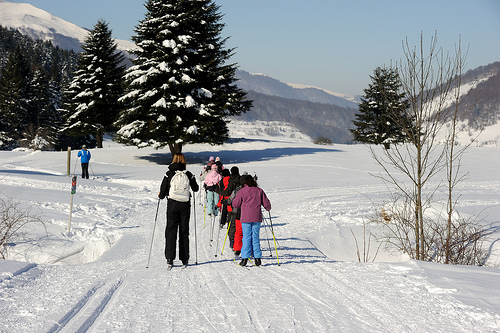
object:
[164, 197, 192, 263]
pants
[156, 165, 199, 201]
jacket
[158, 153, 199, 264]
woman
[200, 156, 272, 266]
people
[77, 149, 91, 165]
jacket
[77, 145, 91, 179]
man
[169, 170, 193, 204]
backpack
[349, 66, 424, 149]
tree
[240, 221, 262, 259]
pants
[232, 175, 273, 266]
person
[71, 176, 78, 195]
sign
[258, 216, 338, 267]
shadows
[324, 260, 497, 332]
snow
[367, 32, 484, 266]
bush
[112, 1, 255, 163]
tree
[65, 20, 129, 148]
tree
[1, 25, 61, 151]
trees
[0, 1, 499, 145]
mountain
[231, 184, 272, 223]
jacket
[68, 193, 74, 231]
sign post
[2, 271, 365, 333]
snow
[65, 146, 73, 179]
pole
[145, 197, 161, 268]
ski pole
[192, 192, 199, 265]
ski pole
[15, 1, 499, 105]
sky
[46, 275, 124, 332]
tracks